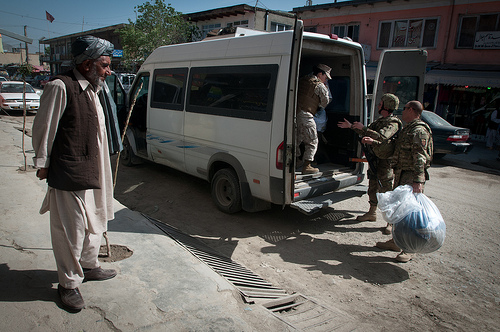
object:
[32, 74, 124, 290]
clothing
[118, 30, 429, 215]
van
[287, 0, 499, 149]
building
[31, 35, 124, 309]
man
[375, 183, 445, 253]
goods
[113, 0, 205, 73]
tree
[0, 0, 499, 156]
background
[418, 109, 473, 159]
sedan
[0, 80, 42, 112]
sedan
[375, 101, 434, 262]
person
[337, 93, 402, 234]
person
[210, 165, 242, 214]
tire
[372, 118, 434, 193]
uniform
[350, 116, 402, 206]
uniform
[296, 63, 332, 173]
person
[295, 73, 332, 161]
uniform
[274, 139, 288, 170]
tail light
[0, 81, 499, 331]
street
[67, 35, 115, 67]
headwrap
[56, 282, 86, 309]
shoes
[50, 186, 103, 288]
pants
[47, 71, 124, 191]
vest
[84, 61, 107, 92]
beard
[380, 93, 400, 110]
helmet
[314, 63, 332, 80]
hat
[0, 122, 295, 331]
sidewalk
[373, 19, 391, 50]
window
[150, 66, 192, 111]
windows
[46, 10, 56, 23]
flag